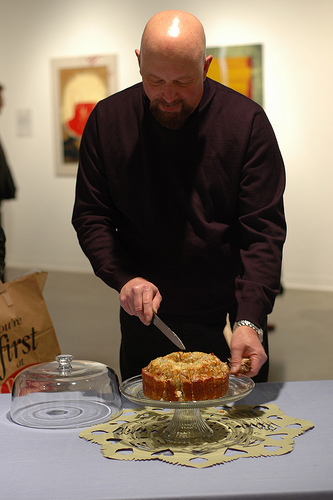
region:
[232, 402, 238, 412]
part of a table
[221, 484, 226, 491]
edge of a table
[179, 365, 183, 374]
part of a cake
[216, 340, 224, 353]
part of a shirt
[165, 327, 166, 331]
part of a knife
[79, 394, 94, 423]
part of a glass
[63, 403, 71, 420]
edge of a bowl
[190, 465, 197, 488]
side of a table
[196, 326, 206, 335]
part of a shirt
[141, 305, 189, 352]
knife blade in hands of man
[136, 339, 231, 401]
dark tan cake on cake dish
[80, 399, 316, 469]
place mat on table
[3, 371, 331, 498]
white table cloth on long table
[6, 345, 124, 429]
glass cake dish cover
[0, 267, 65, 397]
brown shopping bag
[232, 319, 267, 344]
metal watch on wrist of man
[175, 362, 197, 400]
slice marks in cake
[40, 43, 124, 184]
blurred painting on wall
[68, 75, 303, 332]
long sleeve black shirt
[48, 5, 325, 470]
This is a man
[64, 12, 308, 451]
This is a person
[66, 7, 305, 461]
This is a man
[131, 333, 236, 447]
This is a cake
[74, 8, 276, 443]
the man is cutting a cake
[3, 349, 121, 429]
the lid is clear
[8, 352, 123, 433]
the lid is glass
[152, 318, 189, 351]
the knife is pointy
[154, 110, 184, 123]
the man has a beard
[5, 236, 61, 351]
the bag is made of paper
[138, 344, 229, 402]
the cake is brown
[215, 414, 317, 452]
the dollie is tan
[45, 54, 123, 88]
the picture is on the wall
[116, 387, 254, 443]
the cake is on the glass tray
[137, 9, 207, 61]
a man's shinny bald head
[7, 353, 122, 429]
a glass cake cover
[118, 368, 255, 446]
a glass cake plater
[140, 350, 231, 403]
a cut cake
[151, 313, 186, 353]
a sharp stainless steel knife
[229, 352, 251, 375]
a crumpled up brown napkin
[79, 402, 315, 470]
a decritive place mat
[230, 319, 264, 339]
a man's silver watch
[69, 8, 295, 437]
a man cutting a small cake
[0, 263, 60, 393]
a brown paper bag with handles